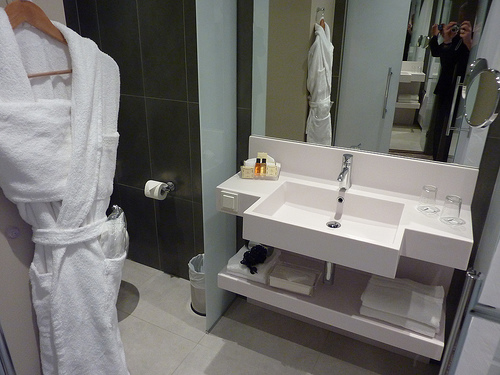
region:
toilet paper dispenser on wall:
[142, 171, 173, 205]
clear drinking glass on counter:
[410, 180, 439, 217]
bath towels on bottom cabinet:
[362, 270, 439, 340]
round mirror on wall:
[461, 57, 498, 128]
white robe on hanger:
[1, 9, 131, 368]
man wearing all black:
[432, 0, 476, 158]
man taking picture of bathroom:
[428, 5, 473, 156]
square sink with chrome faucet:
[248, 138, 404, 265]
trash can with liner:
[172, 246, 214, 318]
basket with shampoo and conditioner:
[240, 144, 285, 182]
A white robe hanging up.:
[2, 3, 142, 370]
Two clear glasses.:
[417, 182, 458, 222]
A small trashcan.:
[186, 245, 207, 320]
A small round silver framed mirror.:
[460, 66, 495, 141]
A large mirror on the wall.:
[263, 0, 489, 170]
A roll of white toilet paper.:
[146, 181, 166, 201]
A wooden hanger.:
[2, 1, 75, 78]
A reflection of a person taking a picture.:
[427, 7, 489, 162]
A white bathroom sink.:
[253, 147, 410, 268]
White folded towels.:
[355, 273, 450, 340]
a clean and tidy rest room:
[52, 4, 479, 370]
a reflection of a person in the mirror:
[416, 0, 483, 168]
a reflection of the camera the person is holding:
[441, 20, 465, 36]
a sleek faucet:
[335, 148, 360, 198]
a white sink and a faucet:
[288, 145, 405, 268]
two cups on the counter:
[411, 166, 465, 232]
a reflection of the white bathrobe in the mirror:
[293, 7, 341, 149]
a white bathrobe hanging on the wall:
[1, 8, 142, 361]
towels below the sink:
[356, 281, 445, 342]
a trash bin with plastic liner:
[183, 250, 210, 323]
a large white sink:
[242, 173, 406, 273]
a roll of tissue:
[143, 179, 165, 199]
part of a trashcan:
[185, 250, 210, 315]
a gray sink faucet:
[335, 145, 355, 195]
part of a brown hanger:
[0, 0, 75, 87]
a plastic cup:
[440, 191, 465, 228]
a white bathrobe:
[1, 15, 131, 373]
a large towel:
[360, 270, 447, 334]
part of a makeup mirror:
[457, 60, 498, 133]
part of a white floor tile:
[122, 263, 170, 326]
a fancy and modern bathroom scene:
[2, 5, 494, 368]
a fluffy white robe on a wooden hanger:
[1, 4, 153, 374]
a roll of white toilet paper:
[140, 174, 172, 204]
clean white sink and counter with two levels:
[216, 127, 482, 364]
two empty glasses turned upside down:
[413, 183, 462, 224]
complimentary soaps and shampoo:
[240, 153, 281, 181]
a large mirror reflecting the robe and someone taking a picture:
[264, 5, 463, 160]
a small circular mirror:
[460, 68, 498, 129]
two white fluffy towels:
[357, 276, 444, 338]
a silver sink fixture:
[337, 150, 353, 195]